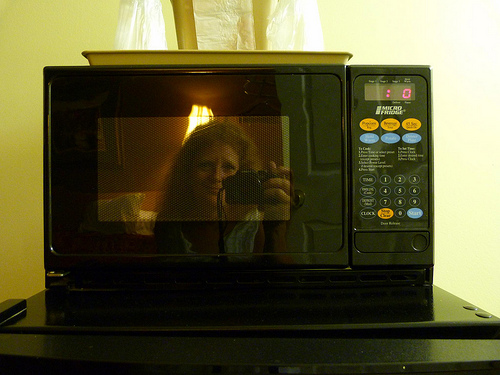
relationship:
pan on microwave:
[80, 50, 353, 67] [42, 63, 435, 289]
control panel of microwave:
[357, 109, 426, 232] [42, 63, 435, 289]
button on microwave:
[402, 205, 428, 224] [34, 32, 439, 324]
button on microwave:
[379, 117, 401, 131] [29, 52, 422, 315]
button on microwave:
[357, 131, 379, 144] [34, 32, 439, 324]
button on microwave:
[402, 131, 420, 146] [42, 63, 435, 289]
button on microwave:
[406, 172, 421, 183] [32, 41, 434, 297]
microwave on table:
[42, 63, 435, 289] [1, 282, 498, 373]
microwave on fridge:
[52, 57, 455, 284] [0, 282, 480, 371]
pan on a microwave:
[76, 44, 354, 74] [33, 64, 460, 291]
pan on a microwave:
[80, 50, 353, 67] [32, 37, 499, 314]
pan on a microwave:
[80, 50, 353, 67] [12, 47, 459, 321]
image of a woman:
[102, 119, 289, 221] [152, 117, 288, 257]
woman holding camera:
[155, 117, 314, 248] [219, 160, 274, 204]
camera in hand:
[219, 160, 274, 204] [249, 160, 299, 212]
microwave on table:
[42, 63, 435, 289] [65, 305, 267, 347]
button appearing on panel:
[357, 107, 429, 227] [349, 73, 433, 265]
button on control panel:
[381, 115, 401, 130] [353, 70, 429, 255]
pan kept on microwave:
[80, 50, 353, 67] [12, 47, 459, 321]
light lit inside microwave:
[184, 101, 221, 138] [42, 63, 435, 289]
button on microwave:
[369, 167, 426, 235] [49, 67, 447, 304]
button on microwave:
[380, 132, 399, 145] [36, 55, 438, 288]